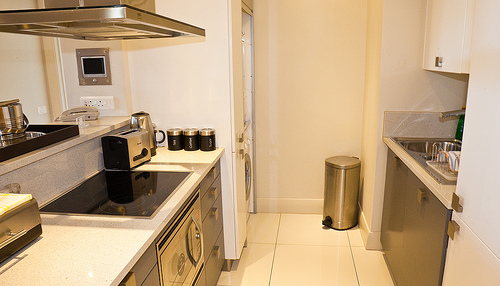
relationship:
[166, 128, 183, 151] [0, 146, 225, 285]
canister on counter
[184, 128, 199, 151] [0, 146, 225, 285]
canister on counter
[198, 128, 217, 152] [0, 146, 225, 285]
canister on counter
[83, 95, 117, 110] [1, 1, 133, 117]
outlets on wall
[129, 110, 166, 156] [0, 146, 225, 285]
cofee maker sitting on countertop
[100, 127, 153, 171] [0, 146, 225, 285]
toaster sitting on countertop